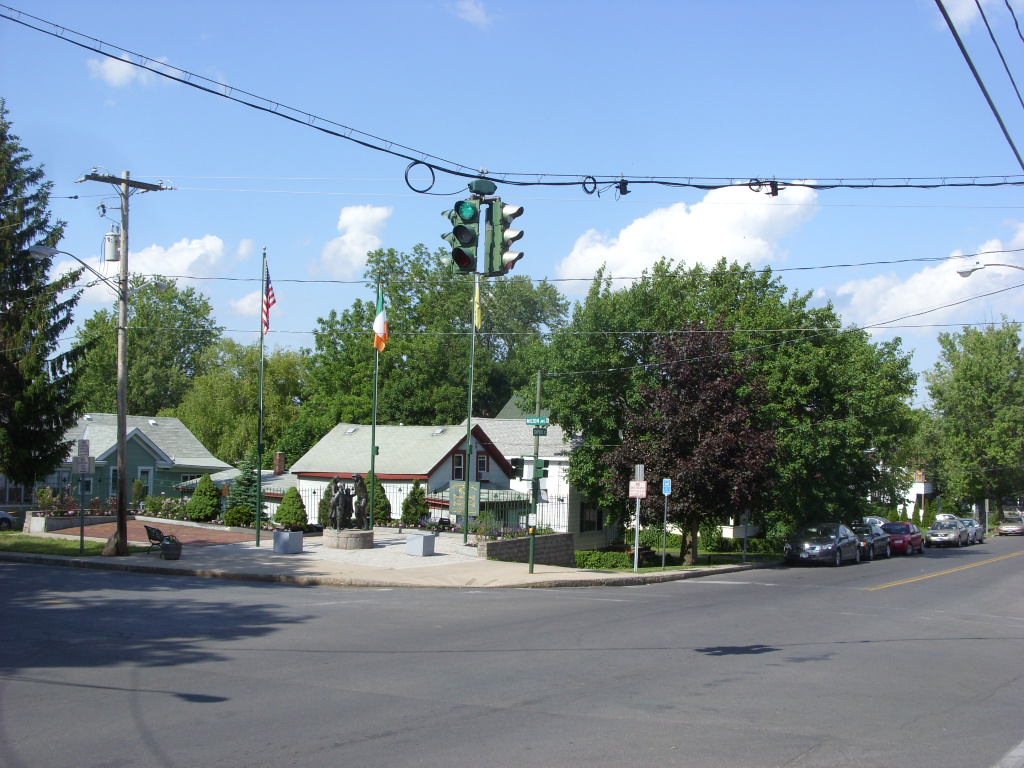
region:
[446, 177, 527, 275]
four way street light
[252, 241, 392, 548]
two flags raised on poles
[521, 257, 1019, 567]
trees lining the street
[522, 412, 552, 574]
street signs on a corner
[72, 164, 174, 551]
electric trasformer on a pole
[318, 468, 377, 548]
statue on a round base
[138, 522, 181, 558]
bench sitting near sidewalk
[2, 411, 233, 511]
green house on the left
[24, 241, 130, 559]
street light on a pole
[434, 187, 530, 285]
Traffic light is green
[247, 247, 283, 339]
American flag is raised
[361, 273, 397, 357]
Green, white and orange flag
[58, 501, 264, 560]
Red brick driveway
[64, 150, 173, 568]
Utility pole on street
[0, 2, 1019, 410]
Blue skies with clouds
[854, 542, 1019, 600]
Yellow line in road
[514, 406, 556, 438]
green street signs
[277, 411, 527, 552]
House with red trim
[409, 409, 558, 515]
red border on white house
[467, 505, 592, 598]
asphalt barrier on side of street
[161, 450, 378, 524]
well cultivated trees in enclosure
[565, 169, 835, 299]
fluffy white clouds in the sky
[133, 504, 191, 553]
bench on the sidewalk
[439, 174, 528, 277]
Traffic light hanging above intersection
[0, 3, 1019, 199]
Electrical wires and cables supporting traffic light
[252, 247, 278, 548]
American flag hanging on flagpole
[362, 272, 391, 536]
Red, white, and green flag on flagpole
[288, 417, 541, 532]
Small white house with gray roof and red trim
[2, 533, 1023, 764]
Paved street meeting at intersection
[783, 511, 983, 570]
Line of cars parked at curb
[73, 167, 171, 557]
Power line pole with transformer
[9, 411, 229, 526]
Gray house with white trim and peaked roof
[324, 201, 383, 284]
A cloud in the sky.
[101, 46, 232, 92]
A cloud in the sky.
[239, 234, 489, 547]
Flags on flagpoles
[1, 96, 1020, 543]
Green leafy trees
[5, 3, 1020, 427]
Power lines hanging over the road.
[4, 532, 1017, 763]
The road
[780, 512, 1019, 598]
Vehicles parked along the side of the road.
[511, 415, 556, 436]
Green and white street signs.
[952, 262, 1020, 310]
A street light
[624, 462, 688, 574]
Signs posted to poles on the sidewalk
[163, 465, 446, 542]
Small evergreen trees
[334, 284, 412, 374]
flag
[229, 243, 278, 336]
United States flag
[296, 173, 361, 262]
white clouds in blue sky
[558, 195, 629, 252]
white clouds in blue sky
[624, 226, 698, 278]
white clouds in blue sky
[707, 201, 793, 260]
white clouds in blue sky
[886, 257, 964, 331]
white clouds in blue sky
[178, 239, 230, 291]
white clouds in blue sky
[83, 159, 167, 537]
a telephone pole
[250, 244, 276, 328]
an american flag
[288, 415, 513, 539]
a small white and red house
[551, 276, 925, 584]
trees lining the street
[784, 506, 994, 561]
cars parked on the street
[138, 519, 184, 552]
a bench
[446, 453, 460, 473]
a window in a house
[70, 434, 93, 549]
a street sign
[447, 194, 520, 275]
a stop light over the road